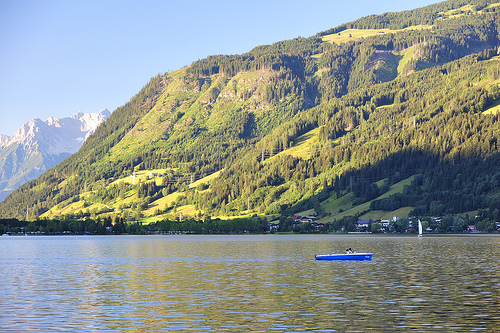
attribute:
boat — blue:
[312, 249, 375, 262]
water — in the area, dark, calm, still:
[2, 261, 499, 332]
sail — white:
[416, 216, 425, 232]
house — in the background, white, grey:
[355, 217, 373, 228]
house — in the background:
[378, 219, 392, 230]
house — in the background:
[297, 213, 318, 221]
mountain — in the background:
[229, 47, 499, 194]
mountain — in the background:
[86, 1, 495, 145]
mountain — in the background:
[2, 107, 113, 192]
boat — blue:
[311, 253, 375, 261]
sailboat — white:
[414, 217, 425, 237]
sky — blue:
[2, 1, 147, 80]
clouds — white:
[26, 26, 82, 59]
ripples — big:
[134, 290, 253, 327]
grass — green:
[121, 121, 171, 148]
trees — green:
[351, 9, 432, 31]